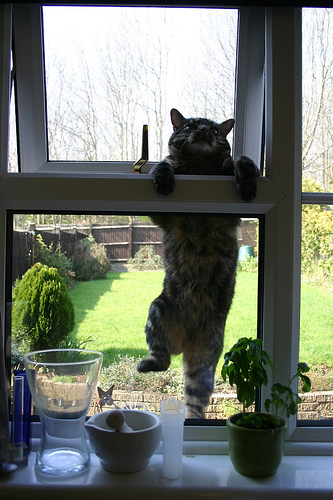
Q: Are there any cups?
A: No, there are no cups.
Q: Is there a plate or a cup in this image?
A: No, there are no cups or plates.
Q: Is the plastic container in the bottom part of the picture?
A: Yes, the container is in the bottom of the image.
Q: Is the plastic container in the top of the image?
A: No, the container is in the bottom of the image.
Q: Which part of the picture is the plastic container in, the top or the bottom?
A: The container is in the bottom of the image.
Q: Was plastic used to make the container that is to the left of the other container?
A: Yes, the container is made of plastic.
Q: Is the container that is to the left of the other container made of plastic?
A: Yes, the container is made of plastic.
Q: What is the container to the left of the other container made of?
A: The container is made of plastic.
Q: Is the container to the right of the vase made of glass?
A: No, the container is made of plastic.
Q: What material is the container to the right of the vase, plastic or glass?
A: The container is made of plastic.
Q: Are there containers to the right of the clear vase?
A: Yes, there is a container to the right of the vase.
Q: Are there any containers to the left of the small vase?
A: No, the container is to the right of the vase.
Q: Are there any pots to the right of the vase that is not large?
A: No, there is a container to the right of the vase.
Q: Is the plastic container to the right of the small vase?
A: Yes, the container is to the right of the vase.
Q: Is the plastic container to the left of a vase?
A: No, the container is to the right of a vase.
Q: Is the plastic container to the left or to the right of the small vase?
A: The container is to the right of the vase.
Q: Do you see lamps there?
A: No, there are no lamps.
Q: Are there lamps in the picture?
A: No, there are no lamps.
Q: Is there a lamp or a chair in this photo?
A: No, there are no lamps or chairs.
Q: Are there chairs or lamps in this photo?
A: No, there are no lamps or chairs.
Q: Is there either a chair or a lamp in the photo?
A: No, there are no lamps or chairs.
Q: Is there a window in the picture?
A: Yes, there is a window.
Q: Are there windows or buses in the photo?
A: Yes, there is a window.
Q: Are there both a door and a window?
A: No, there is a window but no doors.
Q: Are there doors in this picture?
A: No, there are no doors.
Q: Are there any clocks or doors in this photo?
A: No, there are no doors or clocks.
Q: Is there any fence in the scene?
A: Yes, there is a fence.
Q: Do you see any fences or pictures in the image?
A: Yes, there is a fence.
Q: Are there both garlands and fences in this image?
A: No, there is a fence but no garlands.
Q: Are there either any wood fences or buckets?
A: Yes, there is a wood fence.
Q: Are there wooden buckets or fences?
A: Yes, there is a wood fence.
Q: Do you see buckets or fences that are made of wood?
A: Yes, the fence is made of wood.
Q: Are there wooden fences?
A: Yes, there is a wood fence.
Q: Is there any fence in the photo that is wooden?
A: Yes, there is a wood fence.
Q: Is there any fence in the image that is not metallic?
A: Yes, there is a wooden fence.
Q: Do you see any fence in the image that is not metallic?
A: Yes, there is a wooden fence.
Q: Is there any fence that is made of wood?
A: Yes, there is a fence that is made of wood.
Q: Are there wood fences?
A: Yes, there is a fence that is made of wood.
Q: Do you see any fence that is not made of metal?
A: Yes, there is a fence that is made of wood.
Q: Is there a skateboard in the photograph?
A: No, there are no skateboards.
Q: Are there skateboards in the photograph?
A: No, there are no skateboards.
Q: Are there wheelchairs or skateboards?
A: No, there are no skateboards or wheelchairs.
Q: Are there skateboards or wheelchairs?
A: No, there are no skateboards or wheelchairs.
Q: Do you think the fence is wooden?
A: Yes, the fence is wooden.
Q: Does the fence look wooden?
A: Yes, the fence is wooden.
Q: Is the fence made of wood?
A: Yes, the fence is made of wood.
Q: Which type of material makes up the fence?
A: The fence is made of wood.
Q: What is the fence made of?
A: The fence is made of wood.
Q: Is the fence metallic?
A: No, the fence is wooden.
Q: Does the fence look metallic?
A: No, the fence is wooden.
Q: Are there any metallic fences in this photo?
A: No, there is a fence but it is wooden.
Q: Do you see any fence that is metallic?
A: No, there is a fence but it is wooden.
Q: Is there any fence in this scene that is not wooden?
A: No, there is a fence but it is wooden.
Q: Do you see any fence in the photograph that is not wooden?
A: No, there is a fence but it is wooden.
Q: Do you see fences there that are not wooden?
A: No, there is a fence but it is wooden.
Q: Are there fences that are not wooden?
A: No, there is a fence but it is wooden.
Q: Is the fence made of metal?
A: No, the fence is made of wood.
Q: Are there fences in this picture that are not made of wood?
A: No, there is a fence but it is made of wood.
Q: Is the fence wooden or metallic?
A: The fence is wooden.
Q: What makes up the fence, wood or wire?
A: The fence is made of wood.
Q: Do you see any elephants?
A: No, there are no elephants.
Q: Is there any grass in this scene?
A: Yes, there is grass.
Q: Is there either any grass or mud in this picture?
A: Yes, there is grass.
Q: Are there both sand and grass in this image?
A: No, there is grass but no sand.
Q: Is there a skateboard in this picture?
A: No, there are no skateboards.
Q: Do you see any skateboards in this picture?
A: No, there are no skateboards.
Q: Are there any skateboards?
A: No, there are no skateboards.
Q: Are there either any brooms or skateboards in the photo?
A: No, there are no skateboards or brooms.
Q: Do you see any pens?
A: No, there are no pens.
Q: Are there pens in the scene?
A: No, there are no pens.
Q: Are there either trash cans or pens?
A: No, there are no pens or trash cans.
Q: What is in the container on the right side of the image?
A: The plant is in the container.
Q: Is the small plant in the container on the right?
A: Yes, the plant is in the container.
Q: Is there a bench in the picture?
A: No, there are no benches.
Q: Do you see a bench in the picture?
A: No, there are no benches.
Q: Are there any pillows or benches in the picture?
A: No, there are no benches or pillows.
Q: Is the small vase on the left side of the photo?
A: Yes, the vase is on the left of the image.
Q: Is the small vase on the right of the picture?
A: No, the vase is on the left of the image.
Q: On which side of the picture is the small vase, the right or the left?
A: The vase is on the left of the image.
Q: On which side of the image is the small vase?
A: The vase is on the left of the image.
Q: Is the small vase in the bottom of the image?
A: Yes, the vase is in the bottom of the image.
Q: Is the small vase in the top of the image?
A: No, the vase is in the bottom of the image.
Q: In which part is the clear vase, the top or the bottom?
A: The vase is in the bottom of the image.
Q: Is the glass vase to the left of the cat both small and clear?
A: Yes, the vase is small and clear.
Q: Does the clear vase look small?
A: Yes, the vase is small.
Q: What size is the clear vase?
A: The vase is small.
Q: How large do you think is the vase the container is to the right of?
A: The vase is small.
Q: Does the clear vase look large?
A: No, the vase is small.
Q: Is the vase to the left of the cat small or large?
A: The vase is small.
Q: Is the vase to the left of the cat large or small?
A: The vase is small.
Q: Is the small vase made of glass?
A: Yes, the vase is made of glass.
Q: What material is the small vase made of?
A: The vase is made of glass.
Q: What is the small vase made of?
A: The vase is made of glass.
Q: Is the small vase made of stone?
A: No, the vase is made of glass.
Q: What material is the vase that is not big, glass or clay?
A: The vase is made of glass.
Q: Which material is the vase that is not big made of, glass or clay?
A: The vase is made of glass.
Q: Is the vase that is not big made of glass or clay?
A: The vase is made of glass.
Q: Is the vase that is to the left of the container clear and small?
A: Yes, the vase is clear and small.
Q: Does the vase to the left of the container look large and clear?
A: No, the vase is clear but small.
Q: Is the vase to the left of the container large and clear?
A: No, the vase is clear but small.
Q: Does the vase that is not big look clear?
A: Yes, the vase is clear.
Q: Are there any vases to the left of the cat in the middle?
A: Yes, there is a vase to the left of the cat.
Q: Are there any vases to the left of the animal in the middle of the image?
A: Yes, there is a vase to the left of the cat.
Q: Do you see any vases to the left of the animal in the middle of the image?
A: Yes, there is a vase to the left of the cat.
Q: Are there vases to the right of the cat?
A: No, the vase is to the left of the cat.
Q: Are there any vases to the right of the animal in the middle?
A: No, the vase is to the left of the cat.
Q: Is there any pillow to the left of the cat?
A: No, there is a vase to the left of the cat.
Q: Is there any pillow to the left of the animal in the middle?
A: No, there is a vase to the left of the cat.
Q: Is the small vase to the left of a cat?
A: Yes, the vase is to the left of a cat.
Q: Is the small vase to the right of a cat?
A: No, the vase is to the left of a cat.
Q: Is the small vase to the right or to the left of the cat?
A: The vase is to the left of the cat.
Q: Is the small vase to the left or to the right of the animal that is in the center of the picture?
A: The vase is to the left of the cat.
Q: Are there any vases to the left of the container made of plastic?
A: Yes, there is a vase to the left of the container.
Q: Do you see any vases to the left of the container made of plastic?
A: Yes, there is a vase to the left of the container.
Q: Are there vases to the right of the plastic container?
A: No, the vase is to the left of the container.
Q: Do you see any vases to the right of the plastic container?
A: No, the vase is to the left of the container.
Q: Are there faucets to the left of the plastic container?
A: No, there is a vase to the left of the container.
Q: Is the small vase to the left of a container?
A: Yes, the vase is to the left of a container.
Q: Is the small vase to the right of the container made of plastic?
A: No, the vase is to the left of the container.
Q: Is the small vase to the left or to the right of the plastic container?
A: The vase is to the left of the container.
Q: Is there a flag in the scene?
A: No, there are no flags.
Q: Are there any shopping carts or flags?
A: No, there are no flags or shopping carts.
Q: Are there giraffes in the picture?
A: No, there are no giraffes.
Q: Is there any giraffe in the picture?
A: No, there are no giraffes.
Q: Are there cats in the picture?
A: Yes, there is a cat.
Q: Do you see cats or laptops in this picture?
A: Yes, there is a cat.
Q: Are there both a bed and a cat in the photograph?
A: No, there is a cat but no beds.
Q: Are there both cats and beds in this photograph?
A: No, there is a cat but no beds.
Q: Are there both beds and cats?
A: No, there is a cat but no beds.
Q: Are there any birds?
A: No, there are no birds.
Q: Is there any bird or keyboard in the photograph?
A: No, there are no birds or keyboards.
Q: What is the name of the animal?
A: The animal is a cat.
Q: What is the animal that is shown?
A: The animal is a cat.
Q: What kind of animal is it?
A: The animal is a cat.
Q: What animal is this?
A: This is a cat.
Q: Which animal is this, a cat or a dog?
A: This is a cat.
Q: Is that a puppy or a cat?
A: That is a cat.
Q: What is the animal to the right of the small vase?
A: The animal is a cat.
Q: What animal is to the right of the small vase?
A: The animal is a cat.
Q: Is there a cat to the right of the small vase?
A: Yes, there is a cat to the right of the vase.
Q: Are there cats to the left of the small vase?
A: No, the cat is to the right of the vase.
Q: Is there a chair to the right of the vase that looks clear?
A: No, there is a cat to the right of the vase.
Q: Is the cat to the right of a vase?
A: Yes, the cat is to the right of a vase.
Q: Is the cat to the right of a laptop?
A: No, the cat is to the right of a vase.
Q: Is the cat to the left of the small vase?
A: No, the cat is to the right of the vase.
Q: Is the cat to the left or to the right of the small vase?
A: The cat is to the right of the vase.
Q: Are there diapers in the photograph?
A: No, there are no diapers.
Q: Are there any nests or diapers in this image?
A: No, there are no diapers or nests.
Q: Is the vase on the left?
A: Yes, the vase is on the left of the image.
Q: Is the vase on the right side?
A: No, the vase is on the left of the image.